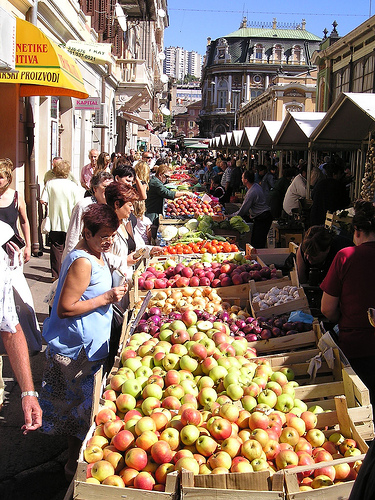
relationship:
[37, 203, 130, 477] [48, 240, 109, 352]
man wearing blue shirt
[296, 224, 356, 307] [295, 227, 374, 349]
woman wearing shirt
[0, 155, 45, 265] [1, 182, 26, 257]
woman wearing top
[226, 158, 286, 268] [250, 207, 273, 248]
man wearing pants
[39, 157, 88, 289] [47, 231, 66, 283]
lady wearing pants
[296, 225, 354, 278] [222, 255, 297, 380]
woman over fruit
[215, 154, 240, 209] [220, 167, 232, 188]
man wearing striped shirt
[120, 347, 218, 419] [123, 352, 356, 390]
apple in crate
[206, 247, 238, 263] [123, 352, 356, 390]
apple in crate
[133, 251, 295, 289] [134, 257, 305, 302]
apples in crate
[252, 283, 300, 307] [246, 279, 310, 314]
white onions are in box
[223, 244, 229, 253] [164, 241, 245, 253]
tomatoes are in box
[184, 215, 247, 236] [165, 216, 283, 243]
lettuce heads in crate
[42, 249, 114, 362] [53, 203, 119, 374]
blue shirt on woman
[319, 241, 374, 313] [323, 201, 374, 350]
shirt on person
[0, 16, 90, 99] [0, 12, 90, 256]
yellow awning on building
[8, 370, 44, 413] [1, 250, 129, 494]
wrist of man